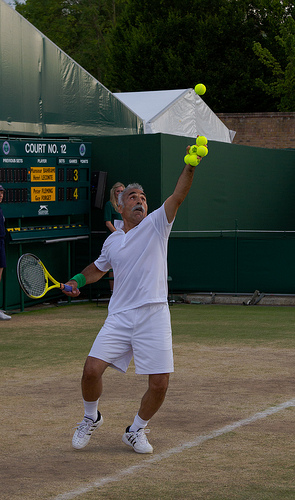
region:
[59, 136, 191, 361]
the man is playing tennis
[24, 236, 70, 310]
the man is playing tennis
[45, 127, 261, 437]
the man is playing tennis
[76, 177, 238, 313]
the man is playing tennis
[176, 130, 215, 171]
hand gripping five yellow tennis balls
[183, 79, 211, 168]
tennis ball floating on top of held balls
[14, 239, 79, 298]
hand holding yellow tennis racket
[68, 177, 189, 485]
player standing behind white line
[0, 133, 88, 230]
dark scoreboard with orange names and numbers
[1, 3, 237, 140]
white and silver tents behind walls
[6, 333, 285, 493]
worn area of grass court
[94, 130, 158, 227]
person standing in corner behind player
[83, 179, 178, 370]
player wearing white t-shirt and white shorts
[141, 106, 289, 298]
green partition in front of brick wall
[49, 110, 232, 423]
this is a tennis player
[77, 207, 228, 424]
the player is wearing white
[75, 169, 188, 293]
the man is old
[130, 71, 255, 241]
these are tennis balls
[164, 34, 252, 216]
the balls are neon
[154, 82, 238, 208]
the balls are green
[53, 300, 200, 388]
the shorts are white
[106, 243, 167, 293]
the shirt is white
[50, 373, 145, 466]
the shoes are white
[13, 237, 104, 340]
the racket is yellow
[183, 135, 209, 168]
hand holding five tennis balls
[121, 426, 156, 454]
a white tennis shoe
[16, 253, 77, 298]
yellow tennis racket with blue handle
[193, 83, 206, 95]
green tennis ball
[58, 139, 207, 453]
a man serving in tennis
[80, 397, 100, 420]
a white cotton sock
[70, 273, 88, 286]
a green wrist band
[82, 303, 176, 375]
white pair of shorts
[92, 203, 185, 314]
white athletic shirt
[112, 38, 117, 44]
a green leaf on a tree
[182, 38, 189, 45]
a green leaf on a tree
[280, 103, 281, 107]
a green leaf on a tree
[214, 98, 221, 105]
a green leaf on a tree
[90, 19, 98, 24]
a green leaf on a tree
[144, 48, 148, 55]
a green leaf on a tree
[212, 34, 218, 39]
a green leaf on a tree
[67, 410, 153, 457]
white shoes with black accents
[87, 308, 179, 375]
white shorts man is wearing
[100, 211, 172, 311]
white shirt man is wearing